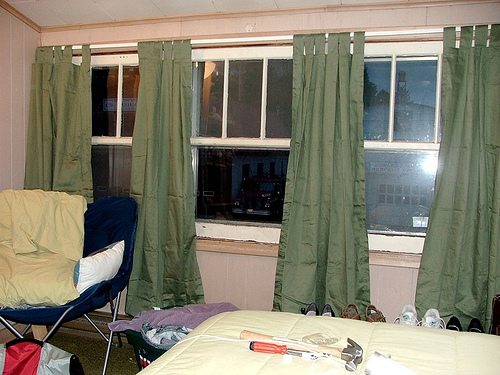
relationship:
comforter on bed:
[191, 299, 435, 373] [203, 267, 417, 371]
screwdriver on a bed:
[249, 340, 311, 357] [128, 307, 498, 374]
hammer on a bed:
[238, 328, 363, 372] [128, 307, 498, 374]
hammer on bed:
[238, 328, 363, 372] [128, 307, 498, 374]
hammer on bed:
[248, 327, 345, 372] [194, 300, 481, 357]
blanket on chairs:
[1, 186, 83, 303] [19, 151, 216, 373]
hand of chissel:
[245, 338, 290, 358] [247, 340, 310, 357]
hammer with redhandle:
[238, 328, 363, 372] [251, 341, 288, 353]